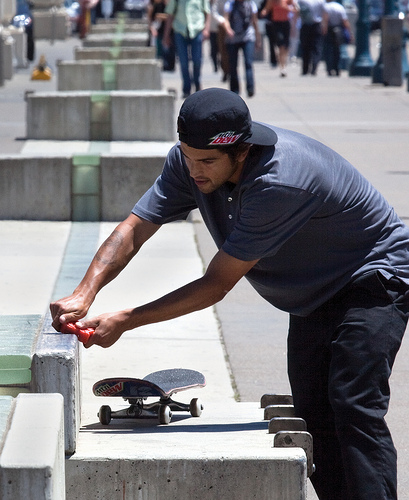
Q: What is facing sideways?
A: A cap.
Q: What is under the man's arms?
A: A skateboard.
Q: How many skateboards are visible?
A: One.